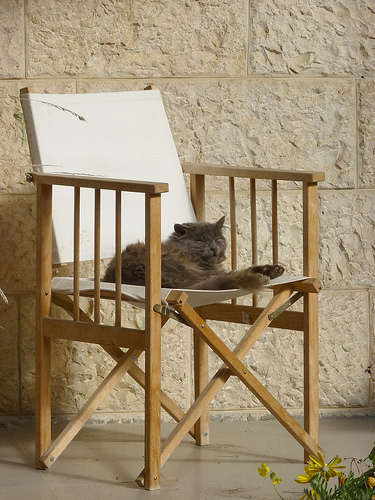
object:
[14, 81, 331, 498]
chair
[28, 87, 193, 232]
cloth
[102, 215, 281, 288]
cat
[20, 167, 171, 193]
arm rest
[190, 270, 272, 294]
tail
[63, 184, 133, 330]
spindles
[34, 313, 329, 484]
legs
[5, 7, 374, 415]
wall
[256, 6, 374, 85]
stone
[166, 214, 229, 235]
ears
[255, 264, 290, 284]
paws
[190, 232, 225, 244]
eyes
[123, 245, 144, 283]
fur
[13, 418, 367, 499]
floor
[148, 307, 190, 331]
hinge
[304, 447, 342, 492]
flower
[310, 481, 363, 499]
leaves